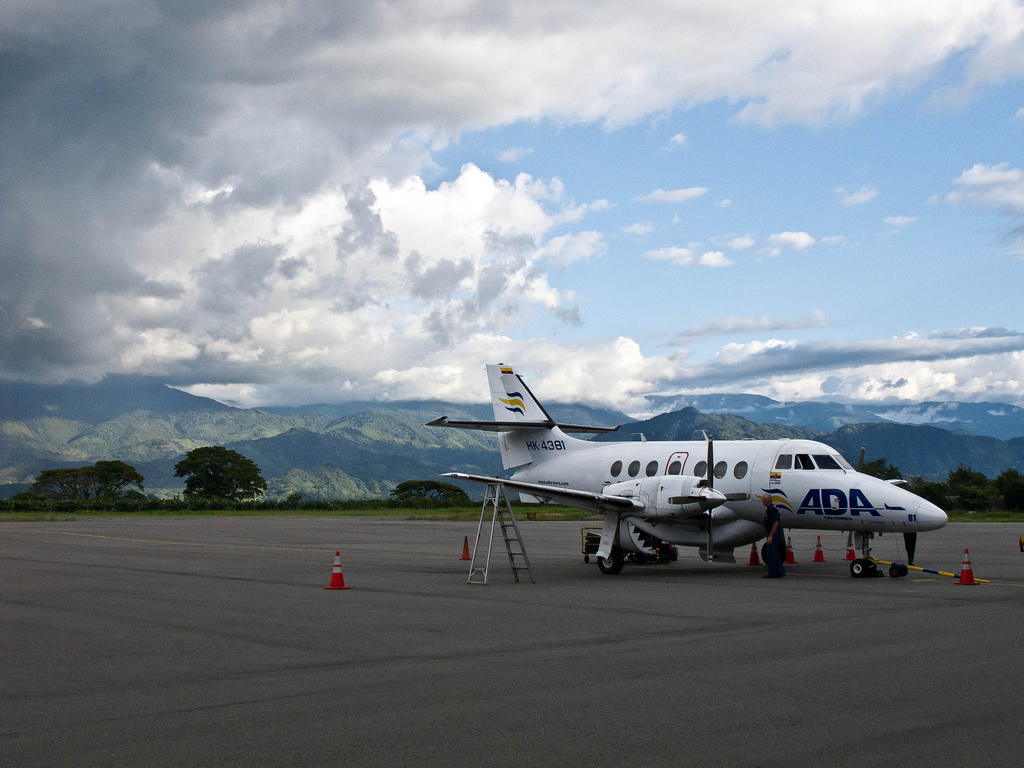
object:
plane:
[425, 363, 948, 586]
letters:
[797, 489, 882, 517]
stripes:
[0, 527, 1024, 588]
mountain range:
[0, 376, 1024, 506]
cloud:
[0, 0, 1024, 410]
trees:
[173, 445, 269, 502]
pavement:
[0, 516, 1024, 768]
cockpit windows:
[774, 454, 793, 471]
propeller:
[666, 432, 751, 566]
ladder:
[466, 483, 535, 586]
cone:
[325, 551, 352, 590]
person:
[759, 494, 787, 579]